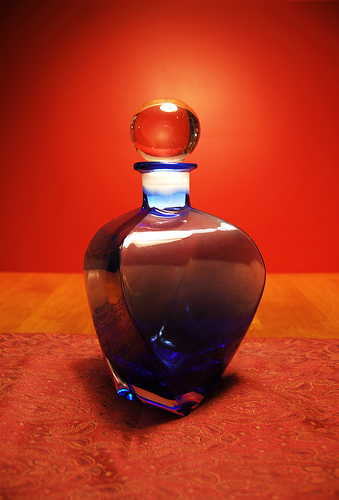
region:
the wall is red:
[15, 106, 247, 280]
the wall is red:
[29, 9, 305, 273]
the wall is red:
[58, 60, 150, 154]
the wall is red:
[135, 143, 292, 305]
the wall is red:
[86, 42, 236, 211]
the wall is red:
[22, 176, 294, 377]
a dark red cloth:
[7, 320, 308, 498]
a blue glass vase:
[86, 153, 280, 410]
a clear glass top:
[126, 86, 216, 164]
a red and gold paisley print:
[5, 397, 146, 486]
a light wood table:
[9, 252, 321, 364]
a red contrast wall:
[16, 31, 336, 280]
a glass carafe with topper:
[77, 106, 271, 410]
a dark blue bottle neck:
[125, 151, 209, 217]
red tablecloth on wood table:
[8, 293, 337, 458]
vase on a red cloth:
[19, 48, 289, 457]